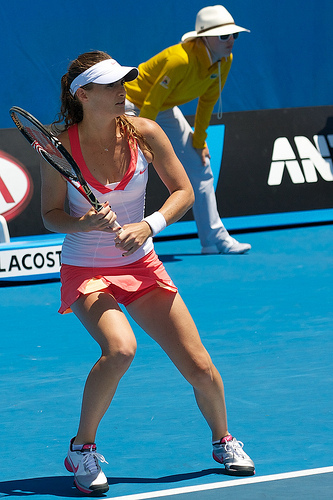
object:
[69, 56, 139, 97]
white visor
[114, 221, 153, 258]
hand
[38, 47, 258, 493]
player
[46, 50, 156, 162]
hair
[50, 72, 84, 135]
ponytail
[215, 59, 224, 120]
string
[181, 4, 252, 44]
hat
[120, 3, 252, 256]
person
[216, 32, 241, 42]
sunglasses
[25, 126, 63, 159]
w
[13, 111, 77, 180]
net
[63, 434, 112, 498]
sneaker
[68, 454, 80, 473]
sign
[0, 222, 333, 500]
tennis court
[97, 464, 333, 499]
line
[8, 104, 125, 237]
racket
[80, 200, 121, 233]
hand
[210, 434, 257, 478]
shoe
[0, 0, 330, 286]
barricade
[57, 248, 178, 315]
skirt